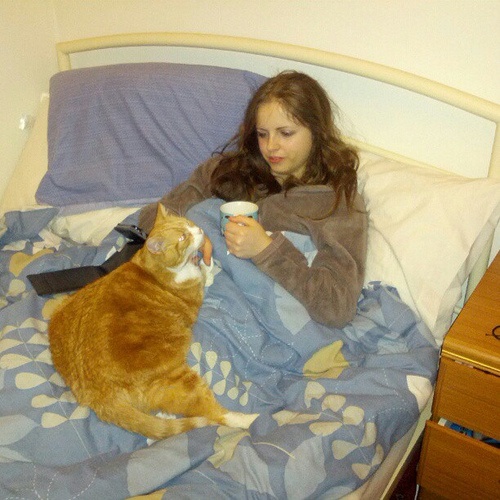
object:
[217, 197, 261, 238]
mug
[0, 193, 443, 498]
comforter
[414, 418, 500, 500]
drawer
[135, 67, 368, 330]
woman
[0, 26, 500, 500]
bed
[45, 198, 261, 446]
cat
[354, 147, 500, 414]
bedsheet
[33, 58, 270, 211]
pillow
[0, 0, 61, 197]
wall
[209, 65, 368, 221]
hair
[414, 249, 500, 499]
cabinet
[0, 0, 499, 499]
bedroom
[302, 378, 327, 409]
design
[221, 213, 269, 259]
hand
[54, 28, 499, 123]
bed post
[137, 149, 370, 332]
sweater